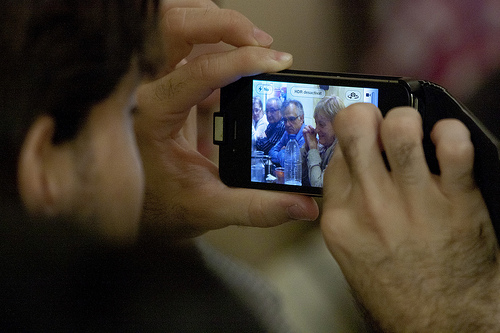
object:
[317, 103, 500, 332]
right hand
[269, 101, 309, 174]
man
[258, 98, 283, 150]
man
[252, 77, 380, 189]
picture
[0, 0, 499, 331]
man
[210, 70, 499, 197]
cell phone